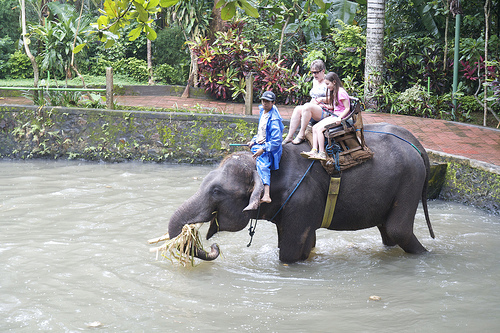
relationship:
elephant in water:
[147, 119, 443, 268] [4, 159, 500, 329]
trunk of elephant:
[161, 207, 222, 264] [147, 119, 443, 268]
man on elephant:
[248, 87, 287, 210] [147, 119, 443, 268]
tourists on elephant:
[280, 59, 334, 145] [147, 119, 443, 268]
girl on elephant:
[292, 72, 353, 169] [147, 119, 443, 268]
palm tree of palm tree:
[362, 0, 387, 112] [364, 0, 388, 109]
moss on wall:
[95, 115, 232, 164] [3, 107, 500, 218]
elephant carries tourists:
[147, 119, 443, 268] [280, 57, 357, 165]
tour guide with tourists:
[248, 87, 287, 210] [280, 57, 357, 165]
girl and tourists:
[292, 72, 353, 169] [280, 59, 334, 145]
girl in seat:
[292, 72, 353, 169] [304, 96, 370, 171]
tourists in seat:
[280, 59, 334, 145] [304, 96, 370, 171]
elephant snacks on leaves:
[147, 119, 443, 268] [167, 222, 202, 267]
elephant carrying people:
[147, 119, 443, 268] [280, 57, 357, 165]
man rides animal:
[248, 87, 287, 210] [147, 119, 443, 268]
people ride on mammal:
[280, 57, 357, 165] [147, 119, 443, 268]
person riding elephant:
[248, 87, 287, 210] [147, 119, 443, 268]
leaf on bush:
[461, 62, 471, 71] [387, 34, 498, 114]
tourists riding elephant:
[280, 57, 357, 165] [147, 119, 443, 268]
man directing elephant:
[248, 87, 287, 210] [147, 119, 443, 268]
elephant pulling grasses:
[147, 119, 443, 268] [167, 222, 202, 267]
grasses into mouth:
[167, 222, 202, 267] [185, 209, 234, 240]